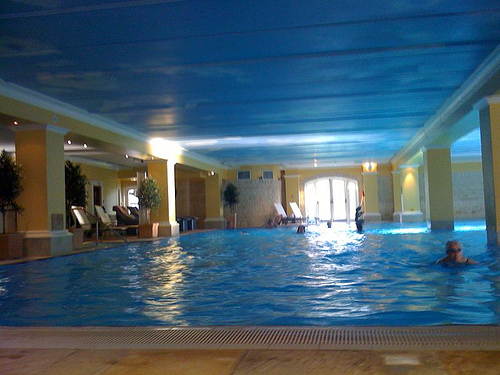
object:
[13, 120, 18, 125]
lighting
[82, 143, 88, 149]
lighting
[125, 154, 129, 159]
lighting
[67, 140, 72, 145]
lighting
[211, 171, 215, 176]
lighting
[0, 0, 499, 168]
ceiling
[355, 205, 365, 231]
ground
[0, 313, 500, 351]
drain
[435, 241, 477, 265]
person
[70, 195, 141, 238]
chair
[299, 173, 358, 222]
doors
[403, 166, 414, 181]
fixture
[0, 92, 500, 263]
wall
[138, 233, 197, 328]
light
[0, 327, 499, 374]
border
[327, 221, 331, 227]
person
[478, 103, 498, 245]
pillar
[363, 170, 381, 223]
pillar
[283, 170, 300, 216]
pillar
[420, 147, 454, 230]
pillar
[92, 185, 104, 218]
doorway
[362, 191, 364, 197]
red item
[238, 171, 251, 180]
vents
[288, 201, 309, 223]
chair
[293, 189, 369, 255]
sunshine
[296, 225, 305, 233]
person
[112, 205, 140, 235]
chair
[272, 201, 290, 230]
chair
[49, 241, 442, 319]
water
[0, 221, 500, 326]
pool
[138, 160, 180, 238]
column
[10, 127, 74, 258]
column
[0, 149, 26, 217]
plant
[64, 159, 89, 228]
plant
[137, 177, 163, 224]
plant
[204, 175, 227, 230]
column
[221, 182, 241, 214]
plant